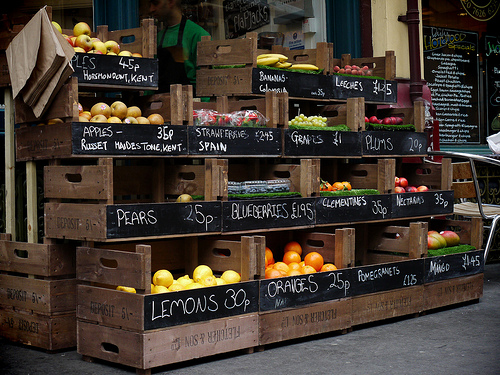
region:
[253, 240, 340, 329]
this bin is for oranges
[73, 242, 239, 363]
this bin is for lemons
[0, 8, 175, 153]
these bins are for apples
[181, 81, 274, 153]
this bin is for strawberries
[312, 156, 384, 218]
this bin is for clementines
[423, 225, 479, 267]
this bin is for mango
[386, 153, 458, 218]
this bin is for nectarines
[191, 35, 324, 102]
this bin is for bananas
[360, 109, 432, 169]
this bin is for plums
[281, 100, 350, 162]
this bin is for grapes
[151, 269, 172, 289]
a round yellow lemon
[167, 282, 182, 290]
a round yellow lemon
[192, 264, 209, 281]
a round yellow lemon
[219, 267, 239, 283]
a round yellow lemon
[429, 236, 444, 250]
a red green mango fruit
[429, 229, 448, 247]
a red green mango fruit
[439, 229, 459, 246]
a red green mango fruit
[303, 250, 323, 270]
an orange fruit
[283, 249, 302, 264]
an orange fruit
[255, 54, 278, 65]
a yellow ripe banana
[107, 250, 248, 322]
This is a box of fruits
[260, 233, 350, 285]
This is a box of fruits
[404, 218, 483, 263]
This is a box of fruits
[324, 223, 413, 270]
This is a box of fruits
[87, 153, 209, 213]
This is a box of fruits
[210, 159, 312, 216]
This is a box of fruits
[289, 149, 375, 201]
This is a box of fruits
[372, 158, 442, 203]
This is a box of fruits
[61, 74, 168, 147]
This is a box of fruits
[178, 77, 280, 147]
This is a box of fruits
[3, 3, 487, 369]
fruit in crates displayed outside a building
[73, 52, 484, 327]
names and prices of fruit written in white chalk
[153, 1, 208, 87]
person wearing a black apron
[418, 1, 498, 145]
a chalkboard sign in shop window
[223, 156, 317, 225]
blueberries in bags sitting in crate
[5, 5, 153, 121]
paper bags on edge of crate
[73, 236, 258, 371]
bright yellow lemons in crate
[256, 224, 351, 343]
large oranges in crate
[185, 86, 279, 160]
containers of strawberries in crate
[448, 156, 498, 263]
a wooden chair with metal legs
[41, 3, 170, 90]
Apples selling for .45 a pound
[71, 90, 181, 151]
Apples selling for .35 a pound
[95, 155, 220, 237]
Pears selling for .25 a pound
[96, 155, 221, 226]
The pears are almost gone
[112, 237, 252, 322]
Lemons selling for .30 a pound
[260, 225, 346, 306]
Oranges selling for .25 a pound.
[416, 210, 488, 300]
Mangos selling for 1.45 each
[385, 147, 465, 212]
Nectarines selling for .35 a pound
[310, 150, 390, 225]
Clementines sell for .35 a pound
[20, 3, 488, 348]
The fruit is in wooden crates